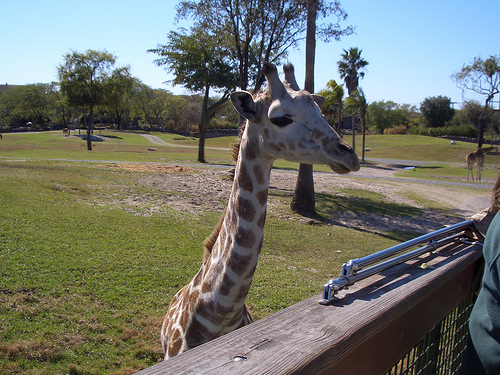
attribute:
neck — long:
[232, 177, 267, 264]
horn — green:
[247, 57, 288, 104]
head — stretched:
[242, 60, 370, 196]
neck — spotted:
[188, 157, 273, 310]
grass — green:
[6, 125, 498, 351]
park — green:
[3, 122, 497, 359]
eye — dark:
[261, 111, 299, 130]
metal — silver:
[320, 217, 476, 304]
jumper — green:
[467, 207, 499, 374]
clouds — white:
[360, 88, 401, 107]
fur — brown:
[158, 128, 340, 360]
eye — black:
[264, 107, 299, 130]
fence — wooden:
[280, 295, 332, 338]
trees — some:
[224, 7, 287, 107]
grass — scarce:
[40, 198, 204, 273]